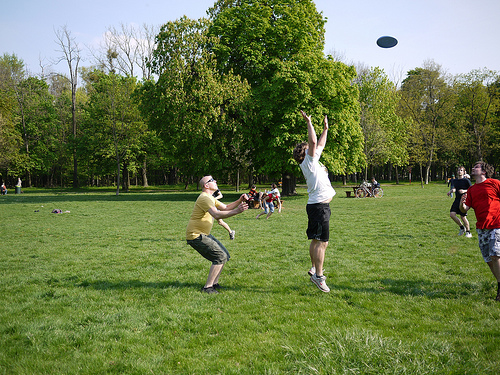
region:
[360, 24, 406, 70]
a frisbee in the air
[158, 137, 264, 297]
A man with sunglasses in a squating position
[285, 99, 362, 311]
a man jumping in the air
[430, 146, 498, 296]
a man wearing a red shirt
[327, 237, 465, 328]
a shadow on the ground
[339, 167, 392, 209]
people sitting by a bench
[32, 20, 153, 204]
bare trees in the background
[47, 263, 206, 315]
a shadow on the ground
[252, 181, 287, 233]
a person in motion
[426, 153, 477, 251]
a man looking up in the air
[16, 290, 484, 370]
The grass is short and green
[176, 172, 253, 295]
The man is playing frisbee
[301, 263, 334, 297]
The shoes of the man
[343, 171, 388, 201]
The bench sitting in the park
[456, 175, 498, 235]
The man has on a red shirt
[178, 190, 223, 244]
The man has on a yellow shirt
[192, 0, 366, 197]
The tree is large with green leaves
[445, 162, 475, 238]
The man has on all black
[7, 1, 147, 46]
The sky is blue and clear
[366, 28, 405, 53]
The frisbee is in the air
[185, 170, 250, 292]
Man with sunglasses getting ready to catch frisbee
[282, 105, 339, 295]
Man with white shirt reaching to catch frisbee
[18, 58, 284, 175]
Many trees in a park setting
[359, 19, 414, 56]
Blue frisbee in the air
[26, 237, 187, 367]
Green grass in a park setting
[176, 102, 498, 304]
Men playing frisbee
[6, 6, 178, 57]
Partly cloudy blue sky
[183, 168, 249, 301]
Man wearing a yellow shirt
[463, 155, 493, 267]
Man wearing a red shirt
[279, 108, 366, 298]
Man wearing black shorts and white shirt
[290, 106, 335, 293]
A man jumping into the air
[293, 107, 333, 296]
A man reaching upward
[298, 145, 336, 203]
A man's white t-shirt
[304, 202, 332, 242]
A man's black shorts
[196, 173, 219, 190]
A man wearing sun glasses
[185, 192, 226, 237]
A man wearing a light yellow t-shirt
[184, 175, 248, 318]
A man standing in green grass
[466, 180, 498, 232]
A man wearing a red t-shirt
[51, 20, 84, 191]
A tree without leaves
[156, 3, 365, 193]
Trees with green leaves